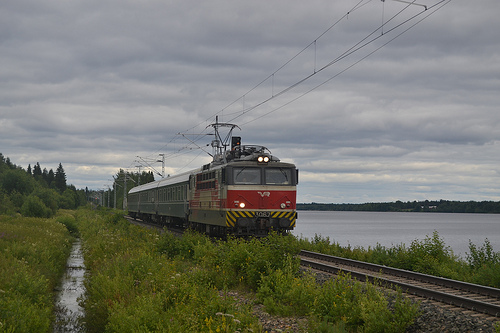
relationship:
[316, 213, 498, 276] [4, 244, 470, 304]
lake in ground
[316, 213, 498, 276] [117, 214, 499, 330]
lake by railroad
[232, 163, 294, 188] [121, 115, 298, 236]
windshield of train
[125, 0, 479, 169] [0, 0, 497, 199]
cables in sky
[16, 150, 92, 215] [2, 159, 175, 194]
trees in distance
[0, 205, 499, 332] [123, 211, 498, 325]
weeds near tracks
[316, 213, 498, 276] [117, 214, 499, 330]
lake near railroad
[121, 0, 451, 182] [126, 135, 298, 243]
cables above train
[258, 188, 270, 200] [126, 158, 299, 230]
number on train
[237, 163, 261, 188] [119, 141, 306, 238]
window on train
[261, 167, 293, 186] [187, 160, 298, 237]
window on train car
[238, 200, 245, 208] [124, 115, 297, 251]
headlight on train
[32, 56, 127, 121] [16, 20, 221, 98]
clouds in sky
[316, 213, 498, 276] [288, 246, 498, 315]
lake by railroad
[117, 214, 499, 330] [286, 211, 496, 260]
railroad by water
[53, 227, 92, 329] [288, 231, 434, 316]
creek by railroad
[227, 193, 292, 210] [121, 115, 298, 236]
headlights on train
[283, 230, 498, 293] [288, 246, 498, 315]
weeds by railroad